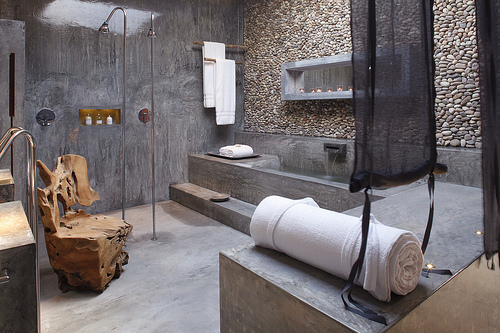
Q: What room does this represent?
A: It represents the bathroom.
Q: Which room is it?
A: It is a bathroom.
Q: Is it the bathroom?
A: Yes, it is the bathroom.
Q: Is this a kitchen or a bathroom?
A: It is a bathroom.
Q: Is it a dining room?
A: No, it is a bathroom.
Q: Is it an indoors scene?
A: Yes, it is indoors.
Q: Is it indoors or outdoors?
A: It is indoors.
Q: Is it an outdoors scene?
A: No, it is indoors.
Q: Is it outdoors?
A: No, it is indoors.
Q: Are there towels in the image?
A: Yes, there is a towel.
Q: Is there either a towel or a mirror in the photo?
A: Yes, there is a towel.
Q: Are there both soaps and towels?
A: No, there is a towel but no soaps.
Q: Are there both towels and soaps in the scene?
A: No, there is a towel but no soaps.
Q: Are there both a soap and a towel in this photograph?
A: No, there is a towel but no soaps.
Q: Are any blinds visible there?
A: No, there are no blinds.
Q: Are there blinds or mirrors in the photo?
A: No, there are no blinds or mirrors.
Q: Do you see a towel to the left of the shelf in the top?
A: Yes, there is a towel to the left of the shelf.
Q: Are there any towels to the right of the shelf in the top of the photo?
A: No, the towel is to the left of the shelf.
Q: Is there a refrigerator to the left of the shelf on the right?
A: No, there is a towel to the left of the shelf.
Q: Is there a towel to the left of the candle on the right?
A: Yes, there is a towel to the left of the candle.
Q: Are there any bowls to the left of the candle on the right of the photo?
A: No, there is a towel to the left of the candle.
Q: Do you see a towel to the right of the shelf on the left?
A: Yes, there is a towel to the right of the shelf.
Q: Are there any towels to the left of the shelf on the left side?
A: No, the towel is to the right of the shelf.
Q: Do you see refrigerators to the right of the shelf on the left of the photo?
A: No, there is a towel to the right of the shelf.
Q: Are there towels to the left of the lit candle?
A: Yes, there is a towel to the left of the candle.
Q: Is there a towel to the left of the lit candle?
A: Yes, there is a towel to the left of the candle.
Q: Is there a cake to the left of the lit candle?
A: No, there is a towel to the left of the candle.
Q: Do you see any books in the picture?
A: No, there are no books.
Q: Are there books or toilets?
A: No, there are no books or toilets.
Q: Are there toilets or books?
A: No, there are no books or toilets.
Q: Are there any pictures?
A: No, there are no pictures.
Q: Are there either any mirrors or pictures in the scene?
A: No, there are no pictures or mirrors.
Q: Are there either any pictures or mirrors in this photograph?
A: No, there are no pictures or mirrors.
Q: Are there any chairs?
A: Yes, there is a chair.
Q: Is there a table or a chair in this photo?
A: Yes, there is a chair.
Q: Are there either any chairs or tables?
A: Yes, there is a chair.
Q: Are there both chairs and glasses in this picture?
A: No, there is a chair but no glasses.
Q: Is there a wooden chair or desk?
A: Yes, there is a wood chair.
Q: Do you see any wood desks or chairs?
A: Yes, there is a wood chair.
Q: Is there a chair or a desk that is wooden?
A: Yes, the chair is wooden.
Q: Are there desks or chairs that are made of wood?
A: Yes, the chair is made of wood.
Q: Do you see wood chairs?
A: Yes, there is a chair that is made of wood.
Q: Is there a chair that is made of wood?
A: Yes, there is a chair that is made of wood.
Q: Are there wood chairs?
A: Yes, there is a chair that is made of wood.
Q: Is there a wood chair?
A: Yes, there is a chair that is made of wood.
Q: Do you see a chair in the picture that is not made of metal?
A: Yes, there is a chair that is made of wood.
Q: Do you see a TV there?
A: No, there are no televisions.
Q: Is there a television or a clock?
A: No, there are no televisions or clocks.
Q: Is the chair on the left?
A: Yes, the chair is on the left of the image.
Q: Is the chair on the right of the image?
A: No, the chair is on the left of the image.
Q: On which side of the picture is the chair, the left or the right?
A: The chair is on the left of the image.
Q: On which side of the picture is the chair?
A: The chair is on the left of the image.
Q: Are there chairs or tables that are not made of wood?
A: No, there is a chair but it is made of wood.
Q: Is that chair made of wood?
A: Yes, the chair is made of wood.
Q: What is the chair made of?
A: The chair is made of wood.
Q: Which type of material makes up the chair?
A: The chair is made of wood.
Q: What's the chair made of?
A: The chair is made of wood.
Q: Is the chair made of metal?
A: No, the chair is made of wood.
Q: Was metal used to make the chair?
A: No, the chair is made of wood.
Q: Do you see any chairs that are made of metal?
A: No, there is a chair but it is made of wood.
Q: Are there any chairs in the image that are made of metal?
A: No, there is a chair but it is made of wood.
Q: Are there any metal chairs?
A: No, there is a chair but it is made of wood.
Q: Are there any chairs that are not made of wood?
A: No, there is a chair but it is made of wood.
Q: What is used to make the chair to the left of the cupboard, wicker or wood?
A: The chair is made of wood.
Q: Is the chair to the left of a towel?
A: Yes, the chair is to the left of a towel.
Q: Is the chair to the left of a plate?
A: No, the chair is to the left of a towel.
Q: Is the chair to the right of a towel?
A: No, the chair is to the left of a towel.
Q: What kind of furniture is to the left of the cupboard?
A: The piece of furniture is a chair.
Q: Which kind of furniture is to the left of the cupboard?
A: The piece of furniture is a chair.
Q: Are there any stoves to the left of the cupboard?
A: No, there is a chair to the left of the cupboard.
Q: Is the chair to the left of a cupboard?
A: Yes, the chair is to the left of a cupboard.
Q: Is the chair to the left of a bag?
A: No, the chair is to the left of a cupboard.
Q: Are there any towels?
A: Yes, there is a towel.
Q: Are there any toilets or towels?
A: Yes, there is a towel.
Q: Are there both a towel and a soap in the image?
A: No, there is a towel but no soaps.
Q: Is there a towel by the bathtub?
A: Yes, there is a towel by the bathtub.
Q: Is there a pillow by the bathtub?
A: No, there is a towel by the bathtub.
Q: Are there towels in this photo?
A: Yes, there is a towel.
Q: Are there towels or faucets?
A: Yes, there is a towel.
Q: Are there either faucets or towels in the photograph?
A: Yes, there is a towel.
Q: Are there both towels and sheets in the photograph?
A: No, there is a towel but no sheets.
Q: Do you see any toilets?
A: No, there are no toilets.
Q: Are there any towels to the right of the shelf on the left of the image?
A: Yes, there is a towel to the right of the shelf.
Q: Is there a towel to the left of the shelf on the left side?
A: No, the towel is to the right of the shelf.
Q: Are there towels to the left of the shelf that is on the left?
A: No, the towel is to the right of the shelf.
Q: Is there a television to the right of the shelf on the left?
A: No, there is a towel to the right of the shelf.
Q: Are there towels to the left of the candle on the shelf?
A: Yes, there is a towel to the left of the candle.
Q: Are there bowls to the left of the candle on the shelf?
A: No, there is a towel to the left of the candle.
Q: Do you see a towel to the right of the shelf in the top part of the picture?
A: No, the towel is to the left of the shelf.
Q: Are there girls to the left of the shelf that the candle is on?
A: No, there is a towel to the left of the shelf.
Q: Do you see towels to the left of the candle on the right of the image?
A: Yes, there is a towel to the left of the candle.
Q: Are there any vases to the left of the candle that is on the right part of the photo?
A: No, there is a towel to the left of the candle.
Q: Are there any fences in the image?
A: No, there are no fences.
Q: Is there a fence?
A: No, there are no fences.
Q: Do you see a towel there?
A: Yes, there is a towel.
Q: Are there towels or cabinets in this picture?
A: Yes, there is a towel.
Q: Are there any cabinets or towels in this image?
A: Yes, there is a towel.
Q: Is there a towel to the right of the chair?
A: Yes, there is a towel to the right of the chair.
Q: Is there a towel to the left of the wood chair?
A: No, the towel is to the right of the chair.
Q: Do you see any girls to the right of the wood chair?
A: No, there is a towel to the right of the chair.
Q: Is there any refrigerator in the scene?
A: No, there are no refrigerators.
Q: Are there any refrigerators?
A: No, there are no refrigerators.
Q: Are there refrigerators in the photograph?
A: No, there are no refrigerators.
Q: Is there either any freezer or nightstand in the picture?
A: No, there are no refrigerators or nightstands.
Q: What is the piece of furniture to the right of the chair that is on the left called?
A: The piece of furniture is a cupboard.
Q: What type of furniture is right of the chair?
A: The piece of furniture is a cupboard.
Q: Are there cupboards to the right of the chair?
A: Yes, there is a cupboard to the right of the chair.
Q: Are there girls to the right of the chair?
A: No, there is a cupboard to the right of the chair.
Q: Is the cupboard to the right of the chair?
A: Yes, the cupboard is to the right of the chair.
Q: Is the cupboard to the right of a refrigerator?
A: No, the cupboard is to the right of the chair.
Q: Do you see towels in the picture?
A: Yes, there is a towel.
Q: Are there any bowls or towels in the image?
A: Yes, there is a towel.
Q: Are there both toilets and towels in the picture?
A: No, there is a towel but no toilets.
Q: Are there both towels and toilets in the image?
A: No, there is a towel but no toilets.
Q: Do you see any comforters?
A: No, there are no comforters.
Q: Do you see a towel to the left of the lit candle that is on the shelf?
A: Yes, there is a towel to the left of the candle.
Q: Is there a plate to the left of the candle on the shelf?
A: No, there is a towel to the left of the candle.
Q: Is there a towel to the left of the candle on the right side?
A: Yes, there is a towel to the left of the candle.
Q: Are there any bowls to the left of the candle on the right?
A: No, there is a towel to the left of the candle.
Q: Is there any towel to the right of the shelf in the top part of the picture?
A: No, the towel is to the left of the shelf.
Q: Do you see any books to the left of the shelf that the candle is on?
A: No, there is a towel to the left of the shelf.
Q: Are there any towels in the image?
A: Yes, there is a towel.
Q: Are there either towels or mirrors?
A: Yes, there is a towel.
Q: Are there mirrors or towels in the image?
A: Yes, there is a towel.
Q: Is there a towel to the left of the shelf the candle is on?
A: Yes, there is a towel to the left of the shelf.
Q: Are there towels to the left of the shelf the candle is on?
A: Yes, there is a towel to the left of the shelf.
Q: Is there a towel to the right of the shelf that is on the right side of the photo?
A: No, the towel is to the left of the shelf.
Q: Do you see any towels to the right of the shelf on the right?
A: No, the towel is to the left of the shelf.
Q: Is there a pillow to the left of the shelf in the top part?
A: No, there is a towel to the left of the shelf.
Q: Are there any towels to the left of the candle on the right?
A: Yes, there is a towel to the left of the candle.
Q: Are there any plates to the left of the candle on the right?
A: No, there is a towel to the left of the candle.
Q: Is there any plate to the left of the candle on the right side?
A: No, there is a towel to the left of the candle.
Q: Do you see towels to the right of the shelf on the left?
A: Yes, there is a towel to the right of the shelf.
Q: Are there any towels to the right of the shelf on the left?
A: Yes, there is a towel to the right of the shelf.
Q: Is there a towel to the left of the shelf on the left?
A: No, the towel is to the right of the shelf.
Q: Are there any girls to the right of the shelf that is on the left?
A: No, there is a towel to the right of the shelf.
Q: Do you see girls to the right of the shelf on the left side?
A: No, there is a towel to the right of the shelf.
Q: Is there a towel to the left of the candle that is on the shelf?
A: Yes, there is a towel to the left of the candle.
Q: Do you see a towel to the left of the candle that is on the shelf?
A: Yes, there is a towel to the left of the candle.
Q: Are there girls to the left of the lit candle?
A: No, there is a towel to the left of the candle.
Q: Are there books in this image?
A: No, there are no books.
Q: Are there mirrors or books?
A: No, there are no books or mirrors.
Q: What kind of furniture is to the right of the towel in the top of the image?
A: The piece of furniture is a shelf.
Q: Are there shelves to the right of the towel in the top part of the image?
A: Yes, there is a shelf to the right of the towel.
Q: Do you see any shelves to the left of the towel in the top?
A: No, the shelf is to the right of the towel.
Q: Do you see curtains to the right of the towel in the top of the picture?
A: No, there is a shelf to the right of the towel.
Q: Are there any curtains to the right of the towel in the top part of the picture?
A: No, there is a shelf to the right of the towel.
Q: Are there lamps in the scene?
A: No, there are no lamps.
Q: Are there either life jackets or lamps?
A: No, there are no lamps or life jackets.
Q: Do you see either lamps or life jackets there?
A: No, there are no lamps or life jackets.